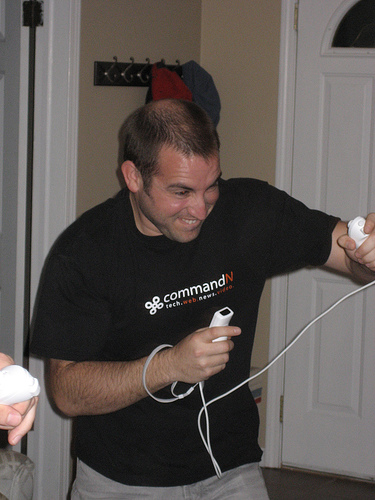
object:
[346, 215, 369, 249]
wii remote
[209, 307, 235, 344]
wii remote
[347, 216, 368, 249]
wii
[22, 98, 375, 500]
man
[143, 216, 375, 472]
nintendo wii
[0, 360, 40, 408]
wii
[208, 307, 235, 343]
wii